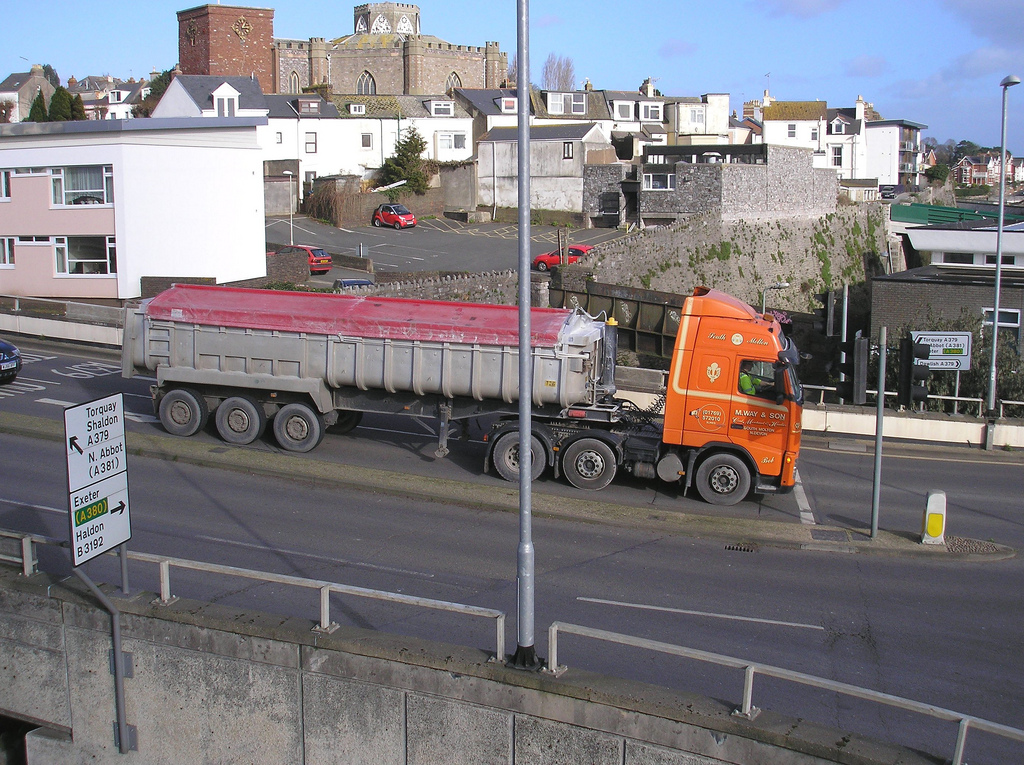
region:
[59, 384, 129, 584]
white signboard with black letters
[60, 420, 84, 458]
black arrow on white signboard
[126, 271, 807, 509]
large truck on the highway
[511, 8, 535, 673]
large gray pole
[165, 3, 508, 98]
big gray bricked castle in the background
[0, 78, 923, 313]
a bunch of houses behind highway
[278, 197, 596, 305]
red c ars parked in street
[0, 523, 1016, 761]
gray rails in the highway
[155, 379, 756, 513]
dark right wheels of big truck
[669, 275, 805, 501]
truck cab is orange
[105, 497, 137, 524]
arrow pointing to the right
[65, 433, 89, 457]
black arrow on the sign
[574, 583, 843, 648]
white line painted on the road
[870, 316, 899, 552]
pole in the street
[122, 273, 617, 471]
red and gray bed of the truck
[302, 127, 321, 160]
window on the white building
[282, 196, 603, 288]
three red cars in a parking lot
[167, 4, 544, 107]
a church made of bricks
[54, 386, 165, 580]
a street sign with arrows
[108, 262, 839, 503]
a large dump truck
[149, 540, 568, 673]
a rail on the side of the road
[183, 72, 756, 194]
a row of houses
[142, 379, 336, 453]
tires on the back of a truck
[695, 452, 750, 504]
black rubber tire with grey metal rim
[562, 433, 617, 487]
black rubber tire with grey metal rim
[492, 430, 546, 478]
black rubber tire with grey metal rim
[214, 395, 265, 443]
black rubber tire with grey metal rim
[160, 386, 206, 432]
black rubber tire with grey metal rim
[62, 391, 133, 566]
street sign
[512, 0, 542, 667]
grey metal light pole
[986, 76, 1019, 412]
grey metal light pole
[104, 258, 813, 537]
the truck on the street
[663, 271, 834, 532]
the cabin is orange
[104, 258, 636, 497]
the truck is covered with red cover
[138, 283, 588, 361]
the cover is red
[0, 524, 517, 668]
a rail over a wall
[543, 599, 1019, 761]
a rail over a wall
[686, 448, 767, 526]
front wheel of truck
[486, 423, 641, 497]
wheels of a truck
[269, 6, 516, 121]
a church with a tower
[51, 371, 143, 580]
the sign is white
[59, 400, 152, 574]
White sign by the road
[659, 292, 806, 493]
Orange cab on a truck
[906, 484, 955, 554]
White post in a median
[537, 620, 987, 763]
Metal rails along a road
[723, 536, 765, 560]
Gutter on a road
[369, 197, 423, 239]
Red car in the background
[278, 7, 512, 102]
Large building made of brick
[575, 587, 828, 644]
White lines on the road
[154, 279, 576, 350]
Red tarp on a truck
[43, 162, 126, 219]
Window on a building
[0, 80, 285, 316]
building on the side of the road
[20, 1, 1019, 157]
the sky above the buildings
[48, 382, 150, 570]
a sign on the structure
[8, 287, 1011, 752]
the road on the ground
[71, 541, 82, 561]
one character on the sign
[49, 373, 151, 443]
the top of the sign